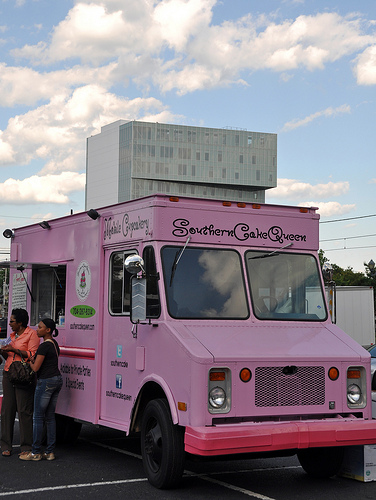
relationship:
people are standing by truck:
[0, 308, 63, 462] [5, 192, 372, 485]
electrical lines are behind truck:
[319, 213, 375, 252] [5, 192, 372, 485]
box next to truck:
[339, 445, 375, 483] [5, 192, 372, 485]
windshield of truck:
[159, 245, 251, 321] [5, 192, 372, 485]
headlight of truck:
[208, 386, 227, 409] [5, 192, 372, 485]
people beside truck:
[0, 308, 63, 462] [5, 192, 372, 485]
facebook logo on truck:
[112, 374, 124, 391] [5, 192, 372, 485]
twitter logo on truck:
[112, 345, 127, 359] [5, 192, 372, 485]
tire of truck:
[296, 446, 344, 476] [5, 192, 372, 485]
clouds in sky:
[2, 2, 375, 205] [0, 0, 376, 274]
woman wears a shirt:
[1, 309, 37, 455] [4, 328, 36, 372]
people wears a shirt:
[17, 311, 67, 465] [35, 337, 60, 379]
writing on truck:
[102, 214, 150, 237] [5, 192, 372, 485]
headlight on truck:
[344, 383, 364, 403] [5, 192, 372, 485]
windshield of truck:
[244, 249, 328, 321] [5, 192, 372, 485]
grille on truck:
[253, 366, 326, 407] [5, 192, 372, 485]